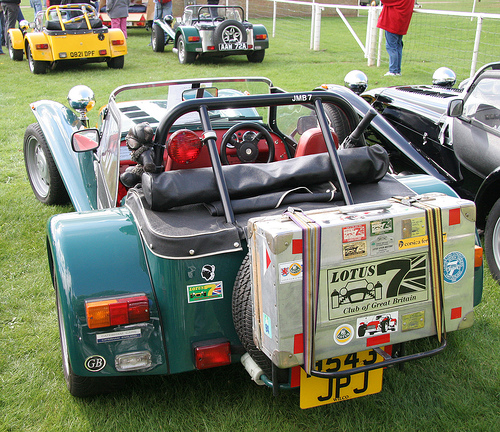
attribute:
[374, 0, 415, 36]
shirt — red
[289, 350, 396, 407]
jpj tag — yellow, black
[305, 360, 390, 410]
tag — black, yellow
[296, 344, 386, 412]
tag — black, yellow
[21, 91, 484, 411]
car — small, green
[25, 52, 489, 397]
buggy — green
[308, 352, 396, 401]
tag — black, yellow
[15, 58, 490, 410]
car — green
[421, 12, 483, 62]
fence — white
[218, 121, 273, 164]
steering wheel — black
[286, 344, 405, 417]
jpj — yellow, black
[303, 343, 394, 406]
license plate — yellow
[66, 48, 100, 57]
license plate — yellow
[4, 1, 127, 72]
buggy — bright yellow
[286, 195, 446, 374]
strap — securing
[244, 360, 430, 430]
yellow tag — black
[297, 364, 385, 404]
license plate — yellow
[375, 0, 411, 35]
jacket — red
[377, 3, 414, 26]
jacket — red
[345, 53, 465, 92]
tag — yellow, black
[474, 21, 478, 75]
fence post — white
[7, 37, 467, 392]
buggy — green 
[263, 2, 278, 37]
post — white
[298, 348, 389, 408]
license plate — yellow, black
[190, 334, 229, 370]
tail light — red